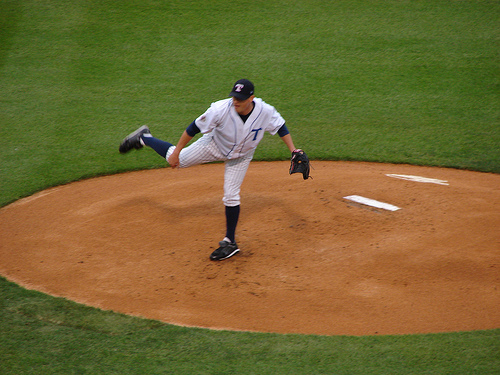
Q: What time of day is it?
A: Daytime.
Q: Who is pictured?
A: Picther.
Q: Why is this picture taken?
A: Photography.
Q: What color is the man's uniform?
A: White.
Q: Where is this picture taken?
A: Bleachers.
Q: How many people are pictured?
A: One.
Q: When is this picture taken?
A: During game.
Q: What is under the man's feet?
A: Dirt.